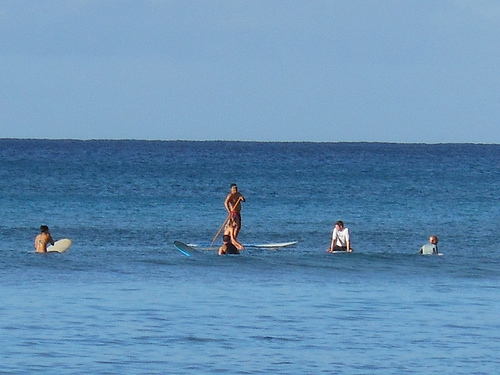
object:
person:
[414, 234, 446, 261]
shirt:
[420, 244, 437, 256]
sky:
[1, 1, 497, 143]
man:
[325, 217, 354, 254]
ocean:
[0, 144, 498, 342]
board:
[186, 240, 299, 250]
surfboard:
[44, 238, 74, 253]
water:
[4, 143, 495, 366]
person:
[35, 221, 56, 254]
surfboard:
[173, 238, 209, 259]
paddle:
[208, 195, 246, 249]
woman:
[223, 216, 246, 251]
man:
[419, 234, 440, 257]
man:
[219, 233, 240, 259]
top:
[223, 241, 240, 254]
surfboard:
[180, 237, 304, 251]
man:
[220, 180, 249, 252]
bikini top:
[32, 239, 45, 245]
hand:
[47, 230, 51, 236]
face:
[45, 226, 48, 234]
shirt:
[330, 227, 350, 248]